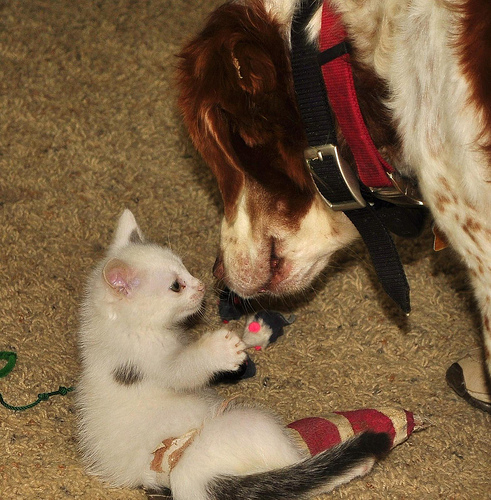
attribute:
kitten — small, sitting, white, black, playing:
[65, 207, 391, 499]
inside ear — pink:
[99, 256, 139, 304]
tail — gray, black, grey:
[195, 425, 395, 499]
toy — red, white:
[286, 406, 434, 464]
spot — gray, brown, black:
[109, 361, 152, 384]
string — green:
[0, 342, 73, 418]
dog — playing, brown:
[172, 1, 490, 300]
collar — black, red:
[289, 0, 410, 305]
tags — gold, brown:
[424, 214, 450, 261]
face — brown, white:
[200, 47, 345, 306]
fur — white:
[92, 306, 169, 467]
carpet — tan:
[4, 9, 173, 207]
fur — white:
[401, 9, 490, 226]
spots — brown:
[433, 169, 490, 247]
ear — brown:
[208, 28, 297, 149]